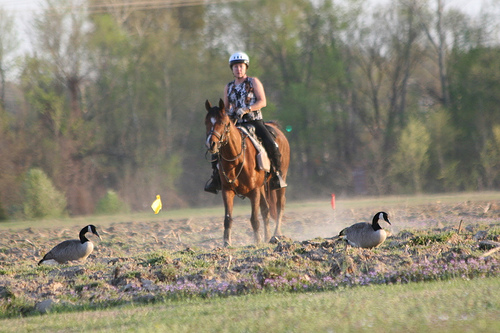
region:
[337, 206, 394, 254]
a large goose in the field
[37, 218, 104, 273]
a large goose in the field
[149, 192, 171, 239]
a yellow flag in the field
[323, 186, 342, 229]
a red flag in the field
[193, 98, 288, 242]
a large brown horse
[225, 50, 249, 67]
a white helmet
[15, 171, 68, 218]
a small bush in the background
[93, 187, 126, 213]
a small bush in the background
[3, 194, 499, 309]
a small field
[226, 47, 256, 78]
the head of a man on a horse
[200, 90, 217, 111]
the ear of the horse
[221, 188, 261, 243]
the front legs of the horse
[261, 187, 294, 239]
the back legs of the horse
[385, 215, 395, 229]
the bird's beak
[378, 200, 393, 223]
the head of the bird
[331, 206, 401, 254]
a bird standing beside the horse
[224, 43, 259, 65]
the helmet on a horse rider's head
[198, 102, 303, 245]
a horse with a man on it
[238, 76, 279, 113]
the hand of a horse rider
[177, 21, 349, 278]
Woman on a horse.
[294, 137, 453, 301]
Goose on the grass.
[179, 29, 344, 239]
Woman wearing a helmet.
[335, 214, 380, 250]
Goose with feathers.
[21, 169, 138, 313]
Goose with a black neck.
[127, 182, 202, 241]
Flag in the field.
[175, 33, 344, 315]
Brown horse with a rider.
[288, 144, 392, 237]
Red flag in the field.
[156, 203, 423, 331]
Green grass on the field.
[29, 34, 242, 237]
Trees in the background.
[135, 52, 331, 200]
this is a horse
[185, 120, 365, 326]
the horse is brown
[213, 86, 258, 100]
this is a woman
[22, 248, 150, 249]
this is a duck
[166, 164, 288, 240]
these are some legs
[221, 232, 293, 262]
this is a hoof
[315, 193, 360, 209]
this is a cone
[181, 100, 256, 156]
this is a head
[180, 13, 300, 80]
this is a helmet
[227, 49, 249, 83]
head of a person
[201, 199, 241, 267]
leg of a horse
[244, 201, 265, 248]
leg of a horse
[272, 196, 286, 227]
leg of a horse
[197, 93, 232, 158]
head of a horse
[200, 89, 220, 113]
ear of a horse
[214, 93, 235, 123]
ear of a horse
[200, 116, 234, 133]
eye of a horse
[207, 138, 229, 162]
mouth of a horse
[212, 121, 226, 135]
an eye of a horse